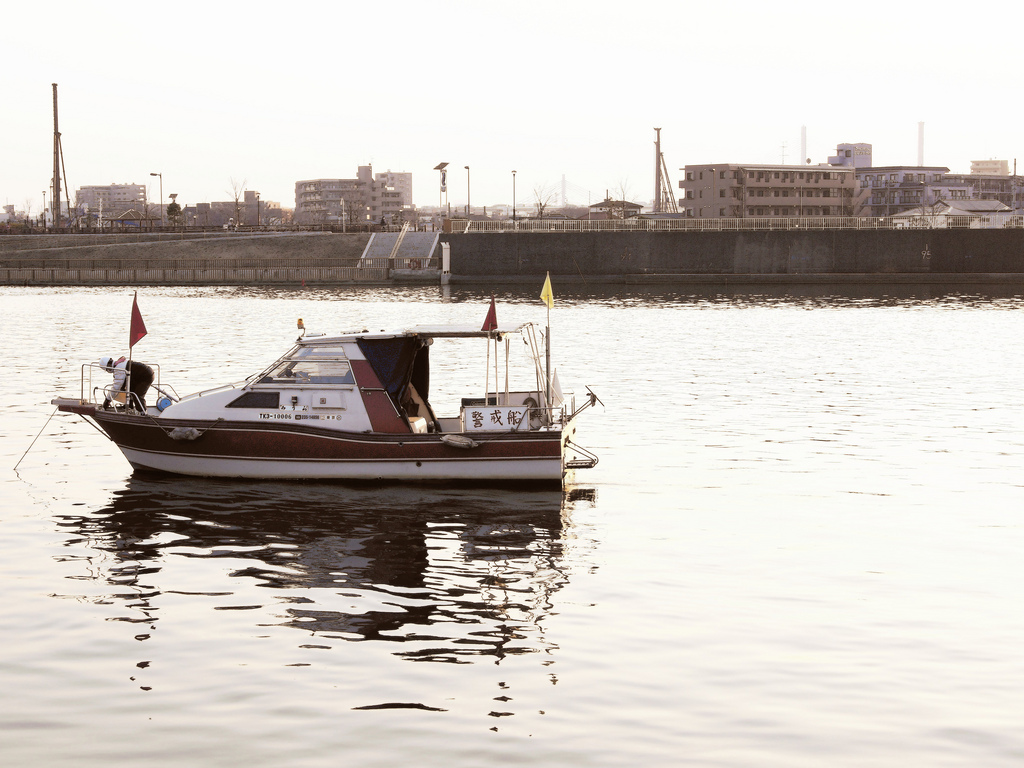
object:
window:
[720, 171, 725, 180]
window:
[720, 189, 726, 198]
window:
[758, 191, 764, 197]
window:
[758, 191, 764, 198]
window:
[830, 188, 839, 197]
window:
[933, 190, 942, 203]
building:
[679, 164, 873, 229]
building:
[970, 160, 1009, 175]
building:
[829, 144, 1024, 228]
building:
[588, 198, 645, 224]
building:
[677, 142, 1022, 229]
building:
[679, 164, 952, 231]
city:
[688, 163, 1017, 222]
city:
[681, 161, 1024, 228]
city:
[69, 144, 1022, 237]